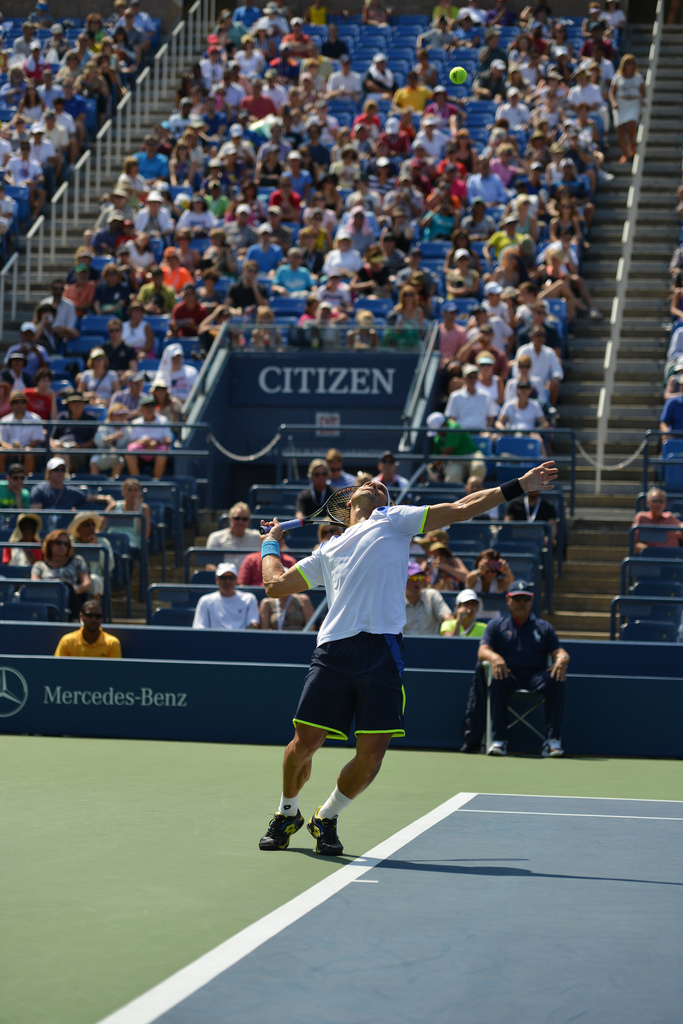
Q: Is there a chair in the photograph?
A: Yes, there is a chair.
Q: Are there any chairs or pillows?
A: Yes, there is a chair.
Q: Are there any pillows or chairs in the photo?
A: Yes, there is a chair.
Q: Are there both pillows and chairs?
A: No, there is a chair but no pillows.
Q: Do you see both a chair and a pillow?
A: No, there is a chair but no pillows.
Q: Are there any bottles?
A: No, there are no bottles.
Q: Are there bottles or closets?
A: No, there are no bottles or closets.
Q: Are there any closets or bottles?
A: No, there are no bottles or closets.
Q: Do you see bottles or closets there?
A: No, there are no bottles or closets.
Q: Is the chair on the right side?
A: Yes, the chair is on the right of the image.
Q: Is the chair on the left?
A: No, the chair is on the right of the image.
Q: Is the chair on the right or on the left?
A: The chair is on the right of the image.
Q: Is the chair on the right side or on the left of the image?
A: The chair is on the right of the image.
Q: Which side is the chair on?
A: The chair is on the right of the image.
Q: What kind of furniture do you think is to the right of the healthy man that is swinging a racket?
A: The piece of furniture is a chair.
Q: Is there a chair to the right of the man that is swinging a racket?
A: Yes, there is a chair to the right of the man.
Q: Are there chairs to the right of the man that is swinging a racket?
A: Yes, there is a chair to the right of the man.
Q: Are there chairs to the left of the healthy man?
A: No, the chair is to the right of the man.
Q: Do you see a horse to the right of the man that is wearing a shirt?
A: No, there is a chair to the right of the man.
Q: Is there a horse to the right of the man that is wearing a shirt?
A: No, there is a chair to the right of the man.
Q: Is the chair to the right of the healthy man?
A: Yes, the chair is to the right of the man.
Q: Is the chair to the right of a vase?
A: No, the chair is to the right of the man.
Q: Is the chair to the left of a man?
A: No, the chair is to the right of a man.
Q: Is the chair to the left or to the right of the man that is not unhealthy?
A: The chair is to the right of the man.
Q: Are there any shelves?
A: No, there are no shelves.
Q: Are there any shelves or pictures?
A: No, there are no shelves or pictures.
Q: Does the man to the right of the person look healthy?
A: Yes, the man is healthy.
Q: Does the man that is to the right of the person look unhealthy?
A: No, the man is healthy.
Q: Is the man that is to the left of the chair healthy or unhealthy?
A: The man is healthy.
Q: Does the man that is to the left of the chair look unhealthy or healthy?
A: The man is healthy.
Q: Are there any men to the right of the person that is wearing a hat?
A: Yes, there is a man to the right of the person.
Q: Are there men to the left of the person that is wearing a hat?
A: No, the man is to the right of the person.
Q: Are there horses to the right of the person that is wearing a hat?
A: No, there is a man to the right of the person.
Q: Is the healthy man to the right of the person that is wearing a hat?
A: Yes, the man is to the right of the person.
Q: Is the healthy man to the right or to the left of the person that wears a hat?
A: The man is to the right of the person.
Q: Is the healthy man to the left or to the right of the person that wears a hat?
A: The man is to the right of the person.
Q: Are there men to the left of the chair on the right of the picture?
A: Yes, there is a man to the left of the chair.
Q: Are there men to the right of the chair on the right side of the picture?
A: No, the man is to the left of the chair.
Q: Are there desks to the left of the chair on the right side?
A: No, there is a man to the left of the chair.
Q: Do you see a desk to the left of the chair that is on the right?
A: No, there is a man to the left of the chair.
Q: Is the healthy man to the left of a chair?
A: Yes, the man is to the left of a chair.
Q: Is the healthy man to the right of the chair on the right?
A: No, the man is to the left of the chair.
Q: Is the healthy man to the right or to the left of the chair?
A: The man is to the left of the chair.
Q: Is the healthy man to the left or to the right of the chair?
A: The man is to the left of the chair.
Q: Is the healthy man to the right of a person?
A: Yes, the man is to the right of a person.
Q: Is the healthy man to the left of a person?
A: No, the man is to the right of a person.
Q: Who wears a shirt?
A: The man wears a shirt.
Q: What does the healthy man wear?
A: The man wears a shirt.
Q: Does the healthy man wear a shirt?
A: Yes, the man wears a shirt.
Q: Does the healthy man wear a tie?
A: No, the man wears a shirt.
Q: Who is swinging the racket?
A: The man is swinging the racket.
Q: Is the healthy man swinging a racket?
A: Yes, the man is swinging a racket.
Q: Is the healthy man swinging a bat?
A: No, the man is swinging a racket.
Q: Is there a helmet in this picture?
A: No, there are no helmets.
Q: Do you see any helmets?
A: No, there are no helmets.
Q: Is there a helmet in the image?
A: No, there are no helmets.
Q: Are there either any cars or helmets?
A: No, there are no helmets or cars.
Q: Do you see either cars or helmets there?
A: No, there are no helmets or cars.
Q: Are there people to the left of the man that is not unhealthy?
A: Yes, there is a person to the left of the man.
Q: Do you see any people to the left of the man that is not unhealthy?
A: Yes, there is a person to the left of the man.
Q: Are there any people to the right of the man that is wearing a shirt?
A: No, the person is to the left of the man.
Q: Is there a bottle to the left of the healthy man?
A: No, there is a person to the left of the man.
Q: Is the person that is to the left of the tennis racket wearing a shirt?
A: Yes, the person is wearing a shirt.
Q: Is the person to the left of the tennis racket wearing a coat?
A: No, the person is wearing a shirt.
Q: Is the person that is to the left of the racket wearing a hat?
A: Yes, the person is wearing a hat.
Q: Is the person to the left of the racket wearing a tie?
A: No, the person is wearing a hat.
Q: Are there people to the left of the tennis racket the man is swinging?
A: Yes, there is a person to the left of the tennis racket.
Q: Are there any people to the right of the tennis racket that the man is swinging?
A: No, the person is to the left of the tennis racket.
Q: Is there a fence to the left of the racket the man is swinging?
A: No, there is a person to the left of the racket.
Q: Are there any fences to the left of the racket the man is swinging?
A: No, there is a person to the left of the racket.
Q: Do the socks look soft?
A: Yes, the socks are soft.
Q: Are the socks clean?
A: Yes, the socks are clean.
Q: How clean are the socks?
A: The socks are clean.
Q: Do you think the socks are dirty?
A: No, the socks are clean.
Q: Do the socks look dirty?
A: No, the socks are clean.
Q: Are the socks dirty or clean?
A: The socks are clean.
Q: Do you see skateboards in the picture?
A: No, there are no skateboards.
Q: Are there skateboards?
A: No, there are no skateboards.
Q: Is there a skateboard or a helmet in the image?
A: No, there are no skateboards or helmets.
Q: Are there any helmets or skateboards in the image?
A: No, there are no skateboards or helmets.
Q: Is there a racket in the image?
A: Yes, there is a racket.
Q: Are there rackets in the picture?
A: Yes, there is a racket.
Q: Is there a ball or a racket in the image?
A: Yes, there is a racket.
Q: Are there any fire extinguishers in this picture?
A: No, there are no fire extinguishers.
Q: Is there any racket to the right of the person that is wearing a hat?
A: Yes, there is a racket to the right of the person.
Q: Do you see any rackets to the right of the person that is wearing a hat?
A: Yes, there is a racket to the right of the person.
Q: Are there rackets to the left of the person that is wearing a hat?
A: No, the racket is to the right of the person.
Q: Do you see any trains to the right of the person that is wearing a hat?
A: No, there is a racket to the right of the person.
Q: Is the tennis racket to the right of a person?
A: Yes, the tennis racket is to the right of a person.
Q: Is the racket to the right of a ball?
A: No, the racket is to the right of a person.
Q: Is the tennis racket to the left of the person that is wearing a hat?
A: No, the tennis racket is to the right of the person.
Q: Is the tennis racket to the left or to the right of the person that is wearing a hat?
A: The tennis racket is to the right of the person.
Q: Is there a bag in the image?
A: No, there are no bags.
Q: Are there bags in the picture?
A: No, there are no bags.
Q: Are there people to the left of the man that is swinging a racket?
A: Yes, there is a person to the left of the man.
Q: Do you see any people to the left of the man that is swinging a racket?
A: Yes, there is a person to the left of the man.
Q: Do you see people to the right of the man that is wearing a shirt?
A: No, the person is to the left of the man.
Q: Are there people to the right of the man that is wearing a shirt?
A: No, the person is to the left of the man.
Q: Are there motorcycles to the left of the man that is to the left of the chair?
A: No, there is a person to the left of the man.